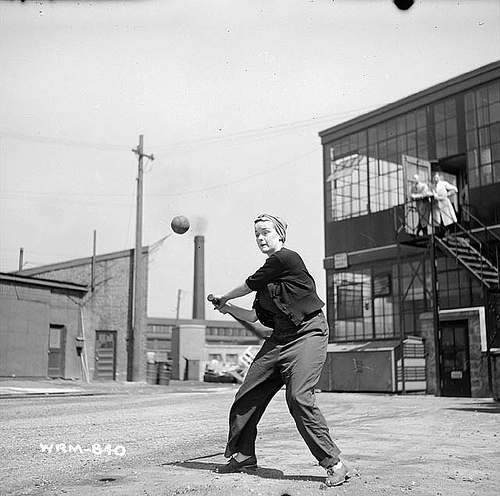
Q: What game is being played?
A: Baseball.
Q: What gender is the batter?
A: Female.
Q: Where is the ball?
A: In the air.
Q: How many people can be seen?
A: 3.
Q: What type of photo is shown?
A: Black and white.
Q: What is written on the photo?
A: Wrm-840.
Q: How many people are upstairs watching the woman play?
A: 2.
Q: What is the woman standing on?
A: Dirt.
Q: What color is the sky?
A: Gray.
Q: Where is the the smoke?
A: Coming from the smokestack.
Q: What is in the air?
A: The ball.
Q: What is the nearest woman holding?
A: A baseball bat.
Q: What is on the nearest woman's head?
A: A hat.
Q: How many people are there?
A: Three.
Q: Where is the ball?
A: In the air.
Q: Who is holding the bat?
A: The nearest woman.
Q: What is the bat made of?
A: Wood.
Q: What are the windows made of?
A: Glass.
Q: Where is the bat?
A: In the batter's hands.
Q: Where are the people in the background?
A: On a fire escape.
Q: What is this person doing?
A: Playing baseball.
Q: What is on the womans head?
A: A hat.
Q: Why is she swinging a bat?
A: To hit the ball.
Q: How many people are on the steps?
A: Two.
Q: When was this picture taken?
A: Daytime.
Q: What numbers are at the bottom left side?
A: 840.